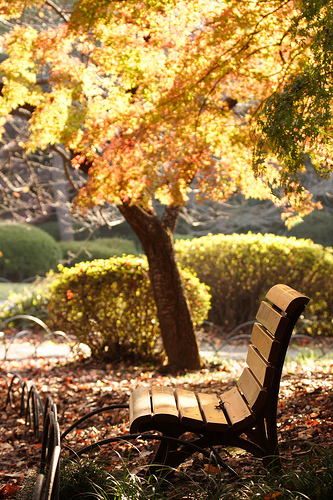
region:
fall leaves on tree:
[15, 13, 286, 186]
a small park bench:
[125, 287, 301, 430]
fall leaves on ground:
[37, 363, 139, 395]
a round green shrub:
[4, 220, 62, 278]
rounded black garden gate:
[5, 374, 72, 492]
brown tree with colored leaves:
[78, 121, 222, 368]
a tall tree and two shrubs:
[39, 249, 327, 329]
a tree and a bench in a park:
[17, 93, 303, 464]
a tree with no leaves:
[3, 140, 84, 222]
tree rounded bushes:
[10, 215, 143, 257]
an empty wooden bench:
[95, 265, 296, 448]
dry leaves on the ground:
[41, 350, 131, 392]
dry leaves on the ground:
[278, 380, 319, 470]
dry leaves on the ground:
[172, 457, 264, 469]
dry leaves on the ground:
[5, 409, 62, 495]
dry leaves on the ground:
[119, 364, 327, 405]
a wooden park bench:
[127, 278, 305, 481]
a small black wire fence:
[3, 368, 59, 494]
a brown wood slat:
[130, 383, 150, 430]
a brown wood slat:
[151, 383, 177, 429]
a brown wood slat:
[174, 385, 202, 431]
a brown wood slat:
[195, 388, 229, 436]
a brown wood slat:
[220, 384, 253, 433]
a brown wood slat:
[236, 367, 266, 415]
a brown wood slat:
[245, 343, 273, 389]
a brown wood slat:
[250, 319, 279, 363]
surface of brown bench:
[122, 375, 229, 424]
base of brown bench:
[146, 440, 201, 487]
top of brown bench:
[240, 279, 320, 360]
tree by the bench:
[122, 278, 238, 357]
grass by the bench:
[77, 456, 162, 496]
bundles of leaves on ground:
[53, 355, 154, 422]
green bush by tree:
[53, 262, 159, 343]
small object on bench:
[205, 392, 237, 410]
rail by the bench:
[10, 371, 74, 472]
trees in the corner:
[2, 258, 51, 296]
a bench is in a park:
[129, 283, 308, 492]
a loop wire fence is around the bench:
[2, 310, 322, 495]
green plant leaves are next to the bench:
[58, 439, 329, 498]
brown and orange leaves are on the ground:
[5, 360, 330, 458]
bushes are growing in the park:
[6, 221, 331, 340]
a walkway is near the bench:
[0, 322, 330, 364]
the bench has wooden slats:
[125, 284, 307, 441]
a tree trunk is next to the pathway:
[55, 121, 209, 370]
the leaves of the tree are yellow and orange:
[13, 70, 329, 225]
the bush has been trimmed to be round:
[0, 218, 65, 281]